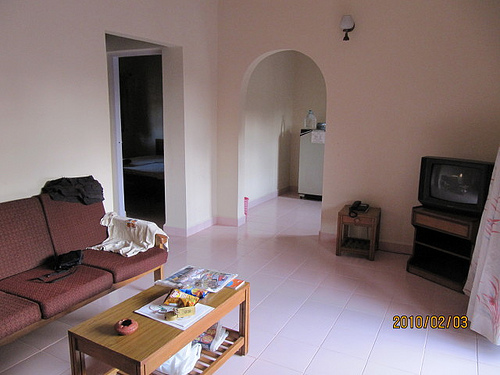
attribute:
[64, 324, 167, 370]
coffee table — wooden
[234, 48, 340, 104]
archway — domed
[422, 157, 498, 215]
tv — black, gray, in corner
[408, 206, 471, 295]
stand — black, brown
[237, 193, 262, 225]
wastebasket — distant, pink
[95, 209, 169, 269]
shirt — white, red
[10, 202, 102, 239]
couch — maroon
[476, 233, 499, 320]
drapes — red, white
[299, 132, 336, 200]
refrigerator — distant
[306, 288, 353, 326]
tile — white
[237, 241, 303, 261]
floor — tile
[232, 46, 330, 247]
doorway — arched, big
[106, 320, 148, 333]
ashtray — pink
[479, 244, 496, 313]
curtains — white, red, floral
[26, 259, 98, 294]
purse — black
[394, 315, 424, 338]
year — 2010